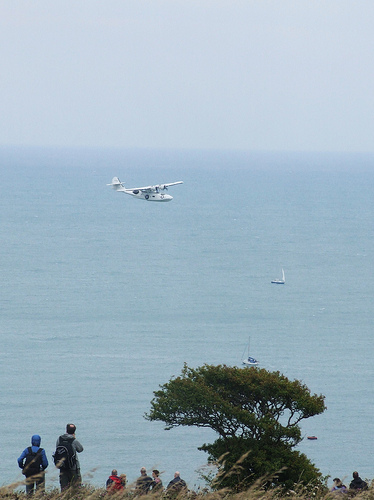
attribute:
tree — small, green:
[146, 357, 327, 498]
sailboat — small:
[270, 266, 288, 289]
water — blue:
[1, 148, 371, 492]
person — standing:
[12, 436, 46, 498]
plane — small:
[104, 174, 185, 206]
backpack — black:
[22, 445, 47, 478]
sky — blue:
[1, 2, 371, 158]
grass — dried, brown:
[3, 458, 371, 499]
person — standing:
[51, 422, 87, 495]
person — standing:
[349, 469, 368, 499]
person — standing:
[148, 470, 164, 492]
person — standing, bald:
[135, 467, 151, 496]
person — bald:
[163, 469, 189, 499]